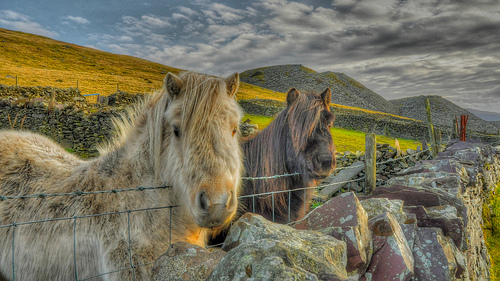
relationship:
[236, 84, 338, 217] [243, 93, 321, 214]
horse has hair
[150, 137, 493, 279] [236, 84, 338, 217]
wall near horse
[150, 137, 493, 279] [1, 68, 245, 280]
wall near horse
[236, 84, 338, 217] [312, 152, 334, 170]
horse has nose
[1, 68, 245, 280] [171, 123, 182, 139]
horse has right eye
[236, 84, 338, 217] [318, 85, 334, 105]
horse has left ear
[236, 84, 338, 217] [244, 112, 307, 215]
horse has neck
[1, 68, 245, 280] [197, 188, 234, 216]
horse has nose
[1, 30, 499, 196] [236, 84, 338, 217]
hillside behind horse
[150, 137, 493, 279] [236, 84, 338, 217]
wall by horse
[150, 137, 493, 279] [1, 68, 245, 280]
wall by horse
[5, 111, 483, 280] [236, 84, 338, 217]
fence in front of horse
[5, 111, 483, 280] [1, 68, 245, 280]
fence in front of horse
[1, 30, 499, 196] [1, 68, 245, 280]
hillside behind horse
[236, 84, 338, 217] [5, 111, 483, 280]
horse by fence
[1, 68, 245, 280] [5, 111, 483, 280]
horse by fence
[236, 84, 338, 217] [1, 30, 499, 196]
horse standing on hillside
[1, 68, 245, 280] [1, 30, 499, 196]
horse standing on hillside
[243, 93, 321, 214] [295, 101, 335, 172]
hair swooping over face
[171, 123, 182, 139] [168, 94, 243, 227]
right eye on side of face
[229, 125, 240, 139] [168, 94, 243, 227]
left eye on side of face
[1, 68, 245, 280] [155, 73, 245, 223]
horse has head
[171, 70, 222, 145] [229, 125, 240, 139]
hair covering left eye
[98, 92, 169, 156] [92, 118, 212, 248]
hair sticking off neck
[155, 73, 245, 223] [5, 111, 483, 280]
head leaning over fence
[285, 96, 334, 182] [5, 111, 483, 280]
head leaning over fence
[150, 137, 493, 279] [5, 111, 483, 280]
wall along fence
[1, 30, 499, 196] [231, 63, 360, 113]
hillside next to hill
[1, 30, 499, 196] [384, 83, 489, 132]
hillside next to hill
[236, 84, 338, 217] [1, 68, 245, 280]
horse next to horse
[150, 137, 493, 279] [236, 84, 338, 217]
wall in front of horse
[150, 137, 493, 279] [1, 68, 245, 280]
wall in front of horse